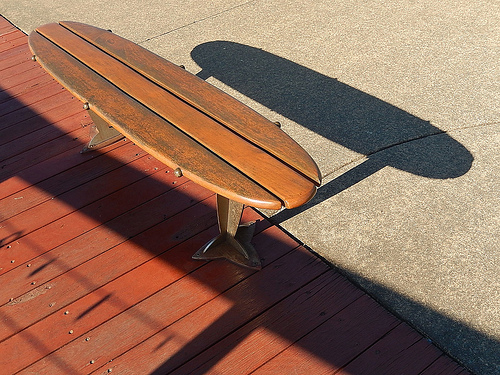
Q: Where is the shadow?
A: Ground.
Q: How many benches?
A: One.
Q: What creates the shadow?
A: Sunshine.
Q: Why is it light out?
A: Day time.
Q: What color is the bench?
A: Brown.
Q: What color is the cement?
A: Gray.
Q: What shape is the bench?
A: Oval.